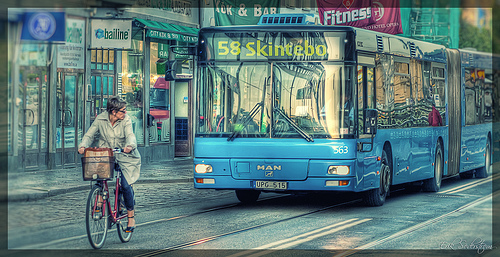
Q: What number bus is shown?
A: 58.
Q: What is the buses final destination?
A: Skintebo.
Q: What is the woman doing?
A: Riding a bike.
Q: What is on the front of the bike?
A: A basket.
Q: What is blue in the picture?
A: Bus.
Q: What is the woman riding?
A: A bicycle.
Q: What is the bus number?
A: 58.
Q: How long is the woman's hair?
A: Short.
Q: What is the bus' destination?
A: Skinebo.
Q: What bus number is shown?
A: 58.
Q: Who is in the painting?
A: A woman.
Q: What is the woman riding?
A: A bike.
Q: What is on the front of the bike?
A: A basket.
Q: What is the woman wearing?
A: A trench coat.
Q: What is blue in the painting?
A: A bus.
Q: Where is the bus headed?
A: Skintebo.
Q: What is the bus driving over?
A: Tracks.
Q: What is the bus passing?
A: Shops.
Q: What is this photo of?
A: A street.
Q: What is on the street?
A: A bus.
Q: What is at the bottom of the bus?
A: Lights.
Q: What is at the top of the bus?
A: Green lettering.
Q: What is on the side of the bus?
A: Buildings.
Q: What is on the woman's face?
A: Glasses.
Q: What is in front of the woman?
A: A basket.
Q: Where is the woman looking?
A: Behind her.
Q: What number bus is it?
A: 58.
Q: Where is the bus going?
A: Skintebo.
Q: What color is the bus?
A: Blue.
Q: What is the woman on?
A: A bike.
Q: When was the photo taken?
A: Day time.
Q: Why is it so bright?
A: Sunny.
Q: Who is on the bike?
A: A woman.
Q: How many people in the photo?
A: One.